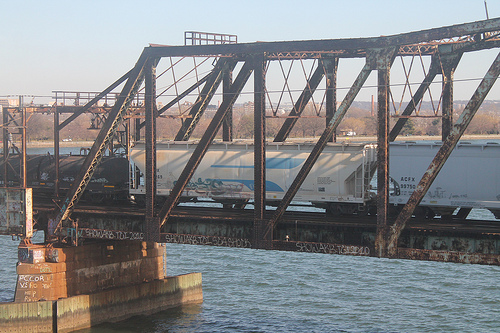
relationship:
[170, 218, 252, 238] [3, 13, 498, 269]
graffiti spray painted on bridge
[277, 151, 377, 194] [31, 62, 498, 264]
white train on bridge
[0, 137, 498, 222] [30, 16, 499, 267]
train crossing bridge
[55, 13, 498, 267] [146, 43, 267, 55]
bridge has beam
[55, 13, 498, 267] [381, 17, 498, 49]
bridge has beam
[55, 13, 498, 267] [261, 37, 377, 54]
bridge has beam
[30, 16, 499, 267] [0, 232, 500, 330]
bridge in water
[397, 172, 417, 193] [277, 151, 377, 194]
black writing is on white train